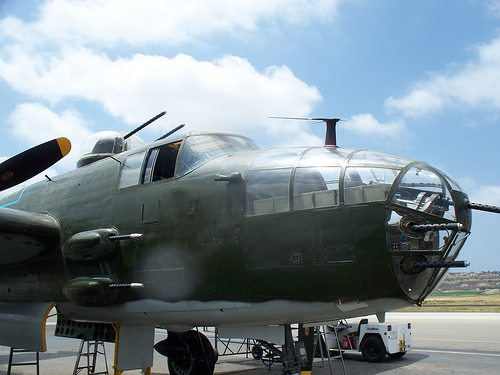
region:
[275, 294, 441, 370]
white airport transport vehicle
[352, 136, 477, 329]
nose of a bomber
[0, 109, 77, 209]
propeller of a bomber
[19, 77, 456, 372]
vintage WWII bomber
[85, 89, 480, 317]
nose and cockpit of bomber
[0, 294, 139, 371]
ladders leading into bomber for repairs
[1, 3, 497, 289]
blue sky with moderate clouds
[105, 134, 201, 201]
window of a vintage bomber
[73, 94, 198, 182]
turret of a bomber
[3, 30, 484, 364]
military airport scene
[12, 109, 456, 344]
old gray airplane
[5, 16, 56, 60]
white clouds in blue sky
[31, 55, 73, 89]
white clouds in blue sky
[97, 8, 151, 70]
white clouds in blue sky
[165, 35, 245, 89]
white clouds in blue sky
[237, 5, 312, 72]
white clouds in blue sky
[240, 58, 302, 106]
white clouds in blue sky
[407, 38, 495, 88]
white clouds in blue sky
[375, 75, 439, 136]
white clouds in blue sky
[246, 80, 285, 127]
part of a cloud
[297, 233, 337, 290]
part of a plane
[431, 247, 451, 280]
part of a metal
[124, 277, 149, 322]
part of a metal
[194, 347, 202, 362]
part of a wheel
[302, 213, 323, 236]
part of a plane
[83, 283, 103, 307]
part of an engine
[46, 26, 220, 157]
These are large clouds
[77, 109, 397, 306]
This is an airplane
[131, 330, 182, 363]
This is a wheel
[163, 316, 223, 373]
The wheel is black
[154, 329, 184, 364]
The wheel is rubber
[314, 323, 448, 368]
This is a small vehicle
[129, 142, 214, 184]
This is a window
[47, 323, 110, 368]
This is a ladder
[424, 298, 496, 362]
This is a tarmack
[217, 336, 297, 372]
There are no people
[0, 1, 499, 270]
the sky is very cloudy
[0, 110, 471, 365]
the plane is on land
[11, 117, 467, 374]
the plane is gray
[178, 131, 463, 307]
the plane has glass in front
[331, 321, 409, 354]
a white vehicle next to plane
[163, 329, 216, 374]
plane has a large wheel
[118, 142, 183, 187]
the plane has windows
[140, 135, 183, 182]
window is open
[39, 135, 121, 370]
plane has yellow accents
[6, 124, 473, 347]
the plane is on the ground